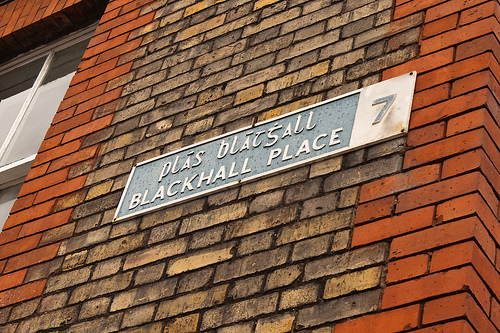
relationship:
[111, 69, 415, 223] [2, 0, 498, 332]
sign on wall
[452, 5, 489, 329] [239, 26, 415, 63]
corner of building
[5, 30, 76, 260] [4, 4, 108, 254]
lines on window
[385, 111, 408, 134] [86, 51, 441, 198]
mark on sign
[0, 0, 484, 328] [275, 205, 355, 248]
building made of brick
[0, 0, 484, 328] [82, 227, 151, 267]
building made of brick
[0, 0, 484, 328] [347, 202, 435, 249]
building made of brick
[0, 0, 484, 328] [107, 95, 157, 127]
building made of brick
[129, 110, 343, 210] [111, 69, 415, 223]
lettering on sign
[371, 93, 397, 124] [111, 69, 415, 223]
number on sign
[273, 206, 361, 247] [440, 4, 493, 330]
bricks are at corner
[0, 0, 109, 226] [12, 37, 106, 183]
window has pane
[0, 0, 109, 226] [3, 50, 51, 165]
window has pane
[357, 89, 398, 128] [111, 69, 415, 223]
number on sign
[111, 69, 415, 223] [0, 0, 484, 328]
sign on building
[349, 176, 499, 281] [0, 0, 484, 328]
bricks on building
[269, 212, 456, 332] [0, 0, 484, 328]
bricks on building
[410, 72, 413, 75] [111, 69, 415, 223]
bolt on sign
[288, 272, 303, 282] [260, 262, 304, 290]
crack in brick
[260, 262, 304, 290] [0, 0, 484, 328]
brick on building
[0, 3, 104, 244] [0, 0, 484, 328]
window on building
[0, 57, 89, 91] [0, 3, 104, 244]
shadow on window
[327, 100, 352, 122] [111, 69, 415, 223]
specks in sign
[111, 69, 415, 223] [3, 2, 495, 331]
sign on building front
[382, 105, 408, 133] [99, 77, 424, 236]
mark on sign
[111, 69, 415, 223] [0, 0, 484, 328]
sign on side of building